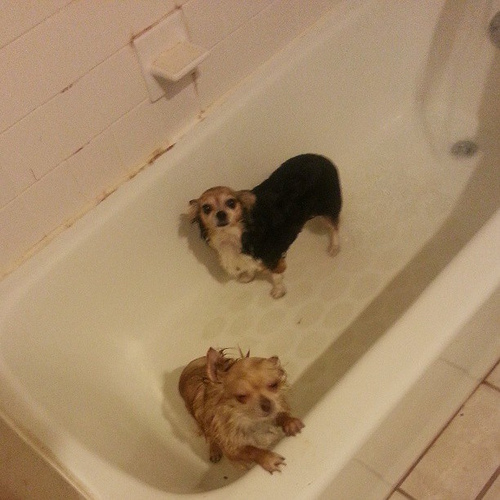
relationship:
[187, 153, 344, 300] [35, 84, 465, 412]
dog inside bathtub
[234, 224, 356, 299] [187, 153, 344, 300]
legs of dog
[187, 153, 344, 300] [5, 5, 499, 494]
dog standing in bathtub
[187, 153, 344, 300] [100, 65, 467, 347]
dog in bathtub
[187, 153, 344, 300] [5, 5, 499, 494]
dog in bathtub